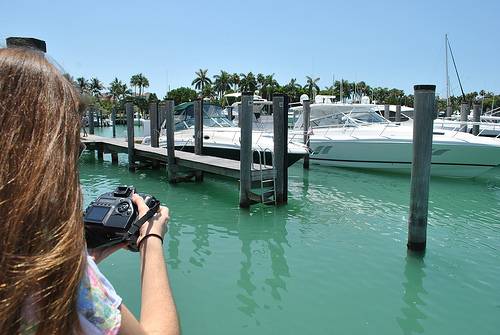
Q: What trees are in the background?
A: Palm trees.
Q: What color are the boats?
A: White.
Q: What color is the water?
A: Green.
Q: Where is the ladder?
A: At the end of the dock.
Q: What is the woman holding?
A: A camera.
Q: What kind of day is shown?
A: Clear blue sky.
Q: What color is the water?
A: Blue green.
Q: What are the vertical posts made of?
A: Wood.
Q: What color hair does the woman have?
A: Brown.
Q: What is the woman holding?
A: Camera.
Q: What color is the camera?
A: Black.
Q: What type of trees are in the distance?
A: Palm.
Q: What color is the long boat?
A: White.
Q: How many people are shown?
A: One.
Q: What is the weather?
A: Sunny.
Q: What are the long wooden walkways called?
A: Dock.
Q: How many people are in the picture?
A: 1.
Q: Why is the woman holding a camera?
A: She is going to take a picture.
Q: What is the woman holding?
A: Camera.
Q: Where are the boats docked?
A: Alongside the harbor.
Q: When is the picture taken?
A: During the daytime.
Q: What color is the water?
A: Turquoise.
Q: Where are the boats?
A: Dock.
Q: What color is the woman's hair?
A: Brown.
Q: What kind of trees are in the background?
A: Palm.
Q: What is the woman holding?
A: A camera.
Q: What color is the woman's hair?
A: Brown.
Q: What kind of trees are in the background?
A: Palm trees.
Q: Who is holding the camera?
A: The woman.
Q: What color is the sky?
A: Blue.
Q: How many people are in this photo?
A: One.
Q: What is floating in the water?
A: The boats.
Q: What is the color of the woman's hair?
A: Brunette.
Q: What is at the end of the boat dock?
A: A ladder.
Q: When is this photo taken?
A: Daytime.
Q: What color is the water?
A: Turquoise.